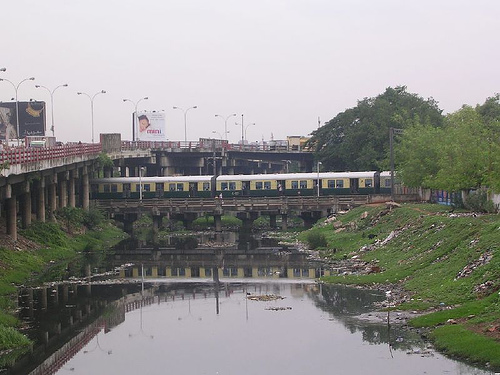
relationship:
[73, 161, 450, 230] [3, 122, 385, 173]
train underneath overpass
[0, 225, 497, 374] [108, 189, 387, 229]
water underneath track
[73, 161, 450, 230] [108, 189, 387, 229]
train over track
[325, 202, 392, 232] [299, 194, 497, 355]
garbage on river banks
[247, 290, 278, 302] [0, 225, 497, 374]
dirt&plastic in water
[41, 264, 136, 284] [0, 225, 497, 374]
dirt&plastic in water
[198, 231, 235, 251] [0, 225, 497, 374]
dirt&plastic in water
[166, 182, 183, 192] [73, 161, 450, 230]
window in train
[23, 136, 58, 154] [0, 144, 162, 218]
truck on over-pass highway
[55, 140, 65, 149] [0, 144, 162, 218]
car on over-pass highway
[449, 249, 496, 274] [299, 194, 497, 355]
trash by river banks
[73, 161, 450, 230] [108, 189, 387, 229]
train on track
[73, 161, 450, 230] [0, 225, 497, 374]
train over water